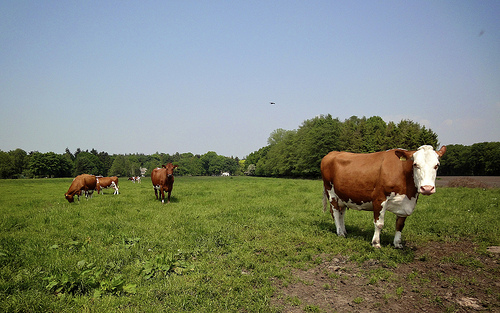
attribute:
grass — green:
[14, 169, 455, 310]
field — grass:
[14, 167, 458, 308]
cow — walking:
[313, 134, 451, 252]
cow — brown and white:
[314, 142, 454, 251]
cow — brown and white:
[89, 172, 123, 195]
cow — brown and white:
[151, 162, 176, 194]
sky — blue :
[4, 3, 485, 181]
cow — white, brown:
[304, 121, 450, 253]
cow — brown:
[49, 170, 104, 205]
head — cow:
[389, 136, 445, 194]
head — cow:
[391, 140, 448, 210]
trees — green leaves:
[10, 136, 240, 176]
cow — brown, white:
[318, 143, 446, 249]